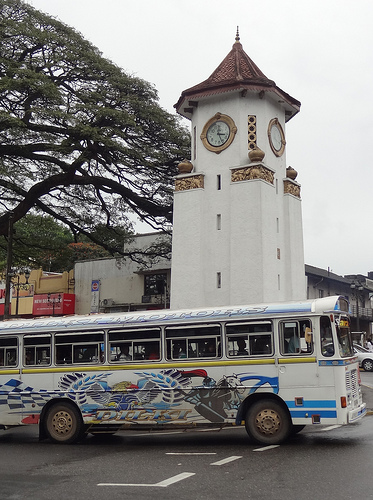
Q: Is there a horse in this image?
A: Yes, there is a horse.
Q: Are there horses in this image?
A: Yes, there is a horse.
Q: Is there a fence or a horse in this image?
A: Yes, there is a horse.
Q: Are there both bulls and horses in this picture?
A: No, there is a horse but no bulls.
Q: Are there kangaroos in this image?
A: No, there are no kangaroos.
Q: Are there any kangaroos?
A: No, there are no kangaroos.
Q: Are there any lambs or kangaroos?
A: No, there are no kangaroos or lambs.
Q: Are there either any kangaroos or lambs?
A: No, there are no kangaroos or lambs.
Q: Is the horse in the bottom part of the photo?
A: Yes, the horse is in the bottom of the image.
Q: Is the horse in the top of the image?
A: No, the horse is in the bottom of the image.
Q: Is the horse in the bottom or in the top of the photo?
A: The horse is in the bottom of the image.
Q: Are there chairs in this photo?
A: No, there are no chairs.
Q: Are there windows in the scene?
A: Yes, there is a window.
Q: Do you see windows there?
A: Yes, there is a window.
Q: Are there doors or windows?
A: Yes, there is a window.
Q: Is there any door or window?
A: Yes, there is a window.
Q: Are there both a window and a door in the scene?
A: No, there is a window but no doors.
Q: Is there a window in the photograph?
A: Yes, there is a window.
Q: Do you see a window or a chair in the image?
A: Yes, there is a window.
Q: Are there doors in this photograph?
A: No, there are no doors.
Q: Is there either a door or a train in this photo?
A: No, there are no doors or trains.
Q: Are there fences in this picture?
A: No, there are no fences.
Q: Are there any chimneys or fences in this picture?
A: No, there are no fences or chimneys.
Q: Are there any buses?
A: Yes, there is a bus.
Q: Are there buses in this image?
A: Yes, there is a bus.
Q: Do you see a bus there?
A: Yes, there is a bus.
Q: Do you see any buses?
A: Yes, there is a bus.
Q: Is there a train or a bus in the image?
A: Yes, there is a bus.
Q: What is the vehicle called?
A: The vehicle is a bus.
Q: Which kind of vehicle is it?
A: The vehicle is a bus.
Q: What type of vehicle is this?
A: This is a bus.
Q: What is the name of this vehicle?
A: This is a bus.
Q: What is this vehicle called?
A: This is a bus.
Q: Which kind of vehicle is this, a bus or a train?
A: This is a bus.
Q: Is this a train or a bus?
A: This is a bus.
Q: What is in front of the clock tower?
A: The bus is in front of the clock tower.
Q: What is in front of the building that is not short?
A: The bus is in front of the clock tower.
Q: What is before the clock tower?
A: The bus is in front of the clock tower.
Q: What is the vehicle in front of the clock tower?
A: The vehicle is a bus.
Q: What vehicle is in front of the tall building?
A: The vehicle is a bus.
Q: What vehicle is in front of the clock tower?
A: The vehicle is a bus.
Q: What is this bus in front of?
A: The bus is in front of the clock tower.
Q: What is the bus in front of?
A: The bus is in front of the clock tower.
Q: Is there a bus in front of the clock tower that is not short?
A: Yes, there is a bus in front of the clock tower.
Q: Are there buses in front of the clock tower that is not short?
A: Yes, there is a bus in front of the clock tower.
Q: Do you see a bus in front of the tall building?
A: Yes, there is a bus in front of the clock tower.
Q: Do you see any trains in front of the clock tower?
A: No, there is a bus in front of the clock tower.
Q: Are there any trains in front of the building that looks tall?
A: No, there is a bus in front of the clock tower.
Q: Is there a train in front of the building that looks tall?
A: No, there is a bus in front of the clock tower.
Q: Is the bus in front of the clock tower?
A: Yes, the bus is in front of the clock tower.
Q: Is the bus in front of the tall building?
A: Yes, the bus is in front of the clock tower.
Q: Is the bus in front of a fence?
A: No, the bus is in front of the clock tower.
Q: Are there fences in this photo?
A: No, there are no fences.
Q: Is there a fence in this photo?
A: No, there are no fences.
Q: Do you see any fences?
A: No, there are no fences.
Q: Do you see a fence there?
A: No, there are no fences.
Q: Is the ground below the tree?
A: Yes, the ground is below the tree.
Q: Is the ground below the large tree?
A: Yes, the ground is below the tree.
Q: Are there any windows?
A: Yes, there is a window.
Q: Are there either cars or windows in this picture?
A: Yes, there is a window.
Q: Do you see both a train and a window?
A: No, there is a window but no trains.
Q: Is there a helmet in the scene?
A: No, there are no helmets.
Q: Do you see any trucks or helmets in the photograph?
A: No, there are no helmets or trucks.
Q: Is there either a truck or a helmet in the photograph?
A: No, there are no helmets or trucks.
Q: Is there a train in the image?
A: No, there are no trains.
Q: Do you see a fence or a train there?
A: No, there are no trains or fences.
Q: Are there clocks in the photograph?
A: Yes, there is a clock.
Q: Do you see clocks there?
A: Yes, there is a clock.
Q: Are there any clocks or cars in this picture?
A: Yes, there is a clock.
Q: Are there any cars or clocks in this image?
A: Yes, there is a clock.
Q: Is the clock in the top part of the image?
A: Yes, the clock is in the top of the image.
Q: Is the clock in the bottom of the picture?
A: No, the clock is in the top of the image.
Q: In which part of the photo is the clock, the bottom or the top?
A: The clock is in the top of the image.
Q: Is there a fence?
A: No, there are no fences.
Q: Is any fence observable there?
A: No, there are no fences.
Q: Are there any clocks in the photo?
A: Yes, there is a clock.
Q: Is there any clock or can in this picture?
A: Yes, there is a clock.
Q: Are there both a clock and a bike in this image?
A: No, there is a clock but no bikes.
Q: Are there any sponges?
A: No, there are no sponges.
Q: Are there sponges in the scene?
A: No, there are no sponges.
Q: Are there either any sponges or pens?
A: No, there are no sponges or pens.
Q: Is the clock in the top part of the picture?
A: Yes, the clock is in the top of the image.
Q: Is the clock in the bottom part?
A: No, the clock is in the top of the image.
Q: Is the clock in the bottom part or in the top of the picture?
A: The clock is in the top of the image.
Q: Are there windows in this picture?
A: Yes, there is a window.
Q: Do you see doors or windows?
A: Yes, there is a window.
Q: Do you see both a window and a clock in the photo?
A: Yes, there are both a window and a clock.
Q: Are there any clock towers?
A: Yes, there is a clock tower.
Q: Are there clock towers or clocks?
A: Yes, there is a clock tower.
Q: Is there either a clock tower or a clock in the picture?
A: Yes, there is a clock tower.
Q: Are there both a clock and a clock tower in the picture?
A: Yes, there are both a clock tower and a clock.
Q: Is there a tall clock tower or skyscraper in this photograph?
A: Yes, there is a tall clock tower.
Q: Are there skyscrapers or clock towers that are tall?
A: Yes, the clock tower is tall.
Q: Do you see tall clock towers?
A: Yes, there is a tall clock tower.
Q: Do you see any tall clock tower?
A: Yes, there is a tall clock tower.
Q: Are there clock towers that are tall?
A: Yes, there is a clock tower that is tall.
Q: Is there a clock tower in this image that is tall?
A: Yes, there is a clock tower that is tall.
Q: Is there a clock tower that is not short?
A: Yes, there is a tall clock tower.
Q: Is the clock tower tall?
A: Yes, the clock tower is tall.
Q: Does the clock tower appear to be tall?
A: Yes, the clock tower is tall.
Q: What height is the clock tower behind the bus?
A: The clock tower is tall.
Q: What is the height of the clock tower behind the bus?
A: The clock tower is tall.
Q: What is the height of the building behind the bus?
A: The clock tower is tall.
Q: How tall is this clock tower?
A: The clock tower is tall.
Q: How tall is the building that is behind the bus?
A: The clock tower is tall.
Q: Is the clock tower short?
A: No, the clock tower is tall.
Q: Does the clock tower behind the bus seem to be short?
A: No, the clock tower is tall.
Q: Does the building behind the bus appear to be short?
A: No, the clock tower is tall.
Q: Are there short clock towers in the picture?
A: No, there is a clock tower but it is tall.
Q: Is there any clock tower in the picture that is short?
A: No, there is a clock tower but it is tall.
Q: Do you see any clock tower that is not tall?
A: No, there is a clock tower but it is tall.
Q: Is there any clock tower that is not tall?
A: No, there is a clock tower but it is tall.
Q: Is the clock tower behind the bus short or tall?
A: The clock tower is tall.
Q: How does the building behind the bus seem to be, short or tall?
A: The clock tower is tall.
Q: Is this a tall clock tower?
A: Yes, this is a tall clock tower.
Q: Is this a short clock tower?
A: No, this is a tall clock tower.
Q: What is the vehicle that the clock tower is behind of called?
A: The vehicle is a bus.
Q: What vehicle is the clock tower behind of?
A: The clock tower is behind the bus.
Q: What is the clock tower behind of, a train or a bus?
A: The clock tower is behind a bus.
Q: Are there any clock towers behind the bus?
A: Yes, there is a clock tower behind the bus.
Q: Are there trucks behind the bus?
A: No, there is a clock tower behind the bus.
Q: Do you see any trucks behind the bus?
A: No, there is a clock tower behind the bus.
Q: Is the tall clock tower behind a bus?
A: Yes, the clock tower is behind a bus.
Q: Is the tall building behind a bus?
A: Yes, the clock tower is behind a bus.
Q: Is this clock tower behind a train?
A: No, the clock tower is behind a bus.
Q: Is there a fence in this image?
A: No, there are no fences.